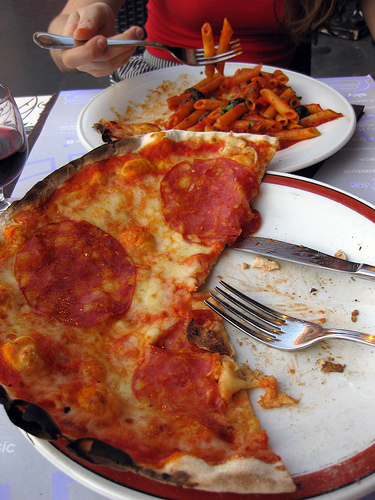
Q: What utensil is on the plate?
A: Fork.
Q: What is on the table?
A: Pizza.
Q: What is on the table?
A: Plate.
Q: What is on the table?
A: Fork.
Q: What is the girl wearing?
A: Shirt.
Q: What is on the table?
A: Plates.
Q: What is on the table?
A: Fork.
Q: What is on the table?
A: Dish.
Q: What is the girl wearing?
A: Red shirt.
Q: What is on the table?
A: Pizza.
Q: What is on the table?
A: Fork.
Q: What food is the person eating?
A: The pasta.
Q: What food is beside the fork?
A: The pizza.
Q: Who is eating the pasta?
A: The woman.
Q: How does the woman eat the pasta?
A: With the fork.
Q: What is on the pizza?
A: Pepperoni.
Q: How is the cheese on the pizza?
A: The cheese is melted.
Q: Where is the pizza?
A: On the plate.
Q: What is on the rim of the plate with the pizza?
A: A red edge.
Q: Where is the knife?
A: Beside the pizza.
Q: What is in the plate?
A: Forks.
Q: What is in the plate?
A: Food.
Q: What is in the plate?
A: Pieces of food.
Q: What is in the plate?
A: Pizza.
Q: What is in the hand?
A: Fork.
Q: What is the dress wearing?
A: Dinner dress.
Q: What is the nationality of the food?
A: Italian.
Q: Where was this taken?
A: Table.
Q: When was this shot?
A: Daytime.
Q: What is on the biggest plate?
A: Pizza.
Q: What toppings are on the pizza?
A: Pepperoni.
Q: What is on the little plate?
A: Pasta.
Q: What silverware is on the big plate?
A: Fork and knife.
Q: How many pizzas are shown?
A: 1.